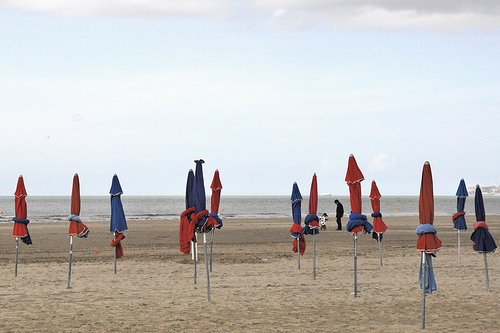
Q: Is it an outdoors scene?
A: Yes, it is outdoors.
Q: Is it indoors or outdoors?
A: It is outdoors.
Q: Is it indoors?
A: No, it is outdoors.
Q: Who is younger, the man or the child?
A: The child is younger than the man.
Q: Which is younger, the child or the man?
A: The child is younger than the man.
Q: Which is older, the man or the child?
A: The man is older than the child.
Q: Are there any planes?
A: No, there are no planes.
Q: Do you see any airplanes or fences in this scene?
A: No, there are no airplanes or fences.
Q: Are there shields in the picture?
A: No, there are no shields.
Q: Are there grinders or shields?
A: No, there are no shields or grinders.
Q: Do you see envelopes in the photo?
A: No, there are no envelopes.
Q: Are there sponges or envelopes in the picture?
A: No, there are no envelopes or sponges.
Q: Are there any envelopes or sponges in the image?
A: No, there are no envelopes or sponges.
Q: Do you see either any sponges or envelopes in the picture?
A: No, there are no envelopes or sponges.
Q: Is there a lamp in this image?
A: No, there are no lamps.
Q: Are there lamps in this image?
A: No, there are no lamps.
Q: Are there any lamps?
A: No, there are no lamps.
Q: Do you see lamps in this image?
A: No, there are no lamps.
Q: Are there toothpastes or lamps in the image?
A: No, there are no lamps or toothpastes.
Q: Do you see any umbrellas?
A: Yes, there is an umbrella.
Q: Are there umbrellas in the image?
A: Yes, there is an umbrella.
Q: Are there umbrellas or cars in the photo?
A: Yes, there is an umbrella.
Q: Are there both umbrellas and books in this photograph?
A: No, there is an umbrella but no books.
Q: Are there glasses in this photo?
A: No, there are no glasses.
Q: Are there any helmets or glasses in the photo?
A: No, there are no glasses or helmets.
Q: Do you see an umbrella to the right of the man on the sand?
A: Yes, there is an umbrella to the right of the man.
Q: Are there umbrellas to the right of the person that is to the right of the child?
A: Yes, there is an umbrella to the right of the man.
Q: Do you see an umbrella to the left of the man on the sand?
A: No, the umbrella is to the right of the man.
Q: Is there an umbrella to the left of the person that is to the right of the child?
A: No, the umbrella is to the right of the man.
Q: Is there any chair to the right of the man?
A: No, there is an umbrella to the right of the man.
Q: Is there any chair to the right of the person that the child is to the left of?
A: No, there is an umbrella to the right of the man.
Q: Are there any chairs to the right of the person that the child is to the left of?
A: No, there is an umbrella to the right of the man.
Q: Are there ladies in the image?
A: No, there are no ladies.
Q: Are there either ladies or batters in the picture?
A: No, there are no ladies or batters.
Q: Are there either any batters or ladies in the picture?
A: No, there are no ladies or batters.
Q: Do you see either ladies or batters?
A: No, there are no ladies or batters.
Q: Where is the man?
A: The man is on the sand.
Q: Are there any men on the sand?
A: Yes, there is a man on the sand.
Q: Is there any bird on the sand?
A: No, there is a man on the sand.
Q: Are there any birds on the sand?
A: No, there is a man on the sand.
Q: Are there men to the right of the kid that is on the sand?
A: Yes, there is a man to the right of the child.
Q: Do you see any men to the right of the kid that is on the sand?
A: Yes, there is a man to the right of the child.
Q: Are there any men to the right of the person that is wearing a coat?
A: Yes, there is a man to the right of the child.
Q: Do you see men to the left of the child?
A: No, the man is to the right of the child.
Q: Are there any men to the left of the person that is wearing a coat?
A: No, the man is to the right of the child.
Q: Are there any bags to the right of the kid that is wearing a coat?
A: No, there is a man to the right of the kid.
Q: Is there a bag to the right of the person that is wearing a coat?
A: No, there is a man to the right of the kid.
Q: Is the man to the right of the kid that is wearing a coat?
A: Yes, the man is to the right of the child.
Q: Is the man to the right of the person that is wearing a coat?
A: Yes, the man is to the right of the child.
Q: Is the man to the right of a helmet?
A: No, the man is to the right of the child.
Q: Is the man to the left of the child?
A: No, the man is to the right of the child.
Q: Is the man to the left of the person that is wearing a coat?
A: No, the man is to the right of the child.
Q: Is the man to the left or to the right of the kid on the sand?
A: The man is to the right of the kid.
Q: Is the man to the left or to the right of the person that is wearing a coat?
A: The man is to the right of the kid.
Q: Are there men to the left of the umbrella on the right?
A: Yes, there is a man to the left of the umbrella.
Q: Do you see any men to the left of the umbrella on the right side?
A: Yes, there is a man to the left of the umbrella.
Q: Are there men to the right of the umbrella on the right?
A: No, the man is to the left of the umbrella.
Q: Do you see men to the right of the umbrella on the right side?
A: No, the man is to the left of the umbrella.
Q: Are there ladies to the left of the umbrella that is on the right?
A: No, there is a man to the left of the umbrella.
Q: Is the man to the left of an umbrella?
A: Yes, the man is to the left of an umbrella.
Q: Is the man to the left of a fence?
A: No, the man is to the left of an umbrella.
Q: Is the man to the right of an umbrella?
A: No, the man is to the left of an umbrella.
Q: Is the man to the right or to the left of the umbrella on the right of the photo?
A: The man is to the left of the umbrella.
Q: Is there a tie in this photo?
A: Yes, there is a tie.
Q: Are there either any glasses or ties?
A: Yes, there is a tie.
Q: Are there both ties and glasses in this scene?
A: No, there is a tie but no glasses.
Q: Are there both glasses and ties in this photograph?
A: No, there is a tie but no glasses.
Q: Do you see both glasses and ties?
A: No, there is a tie but no glasses.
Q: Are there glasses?
A: No, there are no glasses.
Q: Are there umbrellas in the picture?
A: Yes, there is an umbrella.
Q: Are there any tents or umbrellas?
A: Yes, there is an umbrella.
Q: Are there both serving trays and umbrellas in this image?
A: No, there is an umbrella but no serving trays.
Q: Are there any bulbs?
A: No, there are no bulbs.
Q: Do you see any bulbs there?
A: No, there are no bulbs.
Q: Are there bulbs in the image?
A: No, there are no bulbs.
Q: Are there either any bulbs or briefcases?
A: No, there are no bulbs or briefcases.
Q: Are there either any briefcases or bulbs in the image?
A: No, there are no bulbs or briefcases.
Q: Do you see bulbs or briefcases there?
A: No, there are no bulbs or briefcases.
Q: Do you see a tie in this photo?
A: Yes, there is a tie.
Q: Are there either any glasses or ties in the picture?
A: Yes, there is a tie.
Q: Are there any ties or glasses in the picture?
A: Yes, there is a tie.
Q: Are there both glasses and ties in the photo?
A: No, there is a tie but no glasses.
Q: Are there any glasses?
A: No, there are no glasses.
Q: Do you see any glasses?
A: No, there are no glasses.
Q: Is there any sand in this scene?
A: Yes, there is sand.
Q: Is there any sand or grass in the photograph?
A: Yes, there is sand.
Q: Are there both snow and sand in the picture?
A: No, there is sand but no snow.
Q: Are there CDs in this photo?
A: No, there are no cds.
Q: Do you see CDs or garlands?
A: No, there are no CDs or garlands.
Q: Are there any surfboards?
A: No, there are no surfboards.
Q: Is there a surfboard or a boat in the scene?
A: No, there are no surfboards or boats.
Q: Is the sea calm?
A: Yes, the sea is calm.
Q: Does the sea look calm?
A: Yes, the sea is calm.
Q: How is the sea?
A: The sea is calm.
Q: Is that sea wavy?
A: No, the sea is calm.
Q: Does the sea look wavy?
A: No, the sea is calm.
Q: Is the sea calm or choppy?
A: The sea is calm.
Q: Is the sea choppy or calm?
A: The sea is calm.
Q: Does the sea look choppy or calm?
A: The sea is calm.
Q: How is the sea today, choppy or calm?
A: The sea is calm.